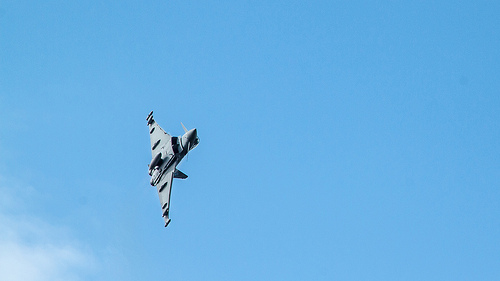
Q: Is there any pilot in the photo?
A: No, there are no pilots.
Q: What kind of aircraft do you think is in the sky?
A: The aircraft is a jet.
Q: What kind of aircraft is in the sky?
A: The aircraft is a jet.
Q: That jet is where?
A: The jet is in the sky.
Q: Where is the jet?
A: The jet is in the sky.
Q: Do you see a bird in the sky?
A: No, there is a jet in the sky.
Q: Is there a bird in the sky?
A: No, there is a jet in the sky.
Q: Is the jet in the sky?
A: Yes, the jet is in the sky.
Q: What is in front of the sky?
A: The jet is in front of the sky.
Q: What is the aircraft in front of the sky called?
A: The aircraft is a jet.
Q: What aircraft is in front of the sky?
A: The aircraft is a jet.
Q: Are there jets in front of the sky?
A: Yes, there is a jet in front of the sky.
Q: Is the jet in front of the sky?
A: Yes, the jet is in front of the sky.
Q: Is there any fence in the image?
A: No, there are no fences.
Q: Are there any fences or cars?
A: No, there are no fences or cars.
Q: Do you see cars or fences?
A: No, there are no fences or cars.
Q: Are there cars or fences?
A: No, there are no fences or cars.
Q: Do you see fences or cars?
A: No, there are no fences or cars.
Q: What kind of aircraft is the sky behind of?
A: The sky is behind the jet.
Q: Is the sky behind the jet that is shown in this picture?
A: Yes, the sky is behind the jet.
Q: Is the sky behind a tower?
A: No, the sky is behind the jet.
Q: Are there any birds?
A: No, there are no birds.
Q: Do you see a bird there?
A: No, there are no birds.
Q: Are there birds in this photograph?
A: No, there are no birds.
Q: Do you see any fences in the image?
A: No, there are no fences.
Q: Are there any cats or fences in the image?
A: No, there are no fences or cats.